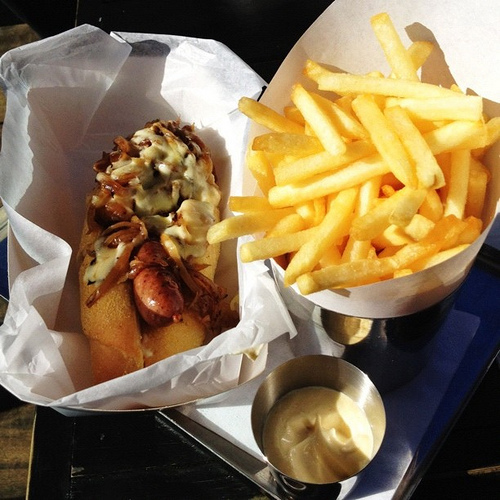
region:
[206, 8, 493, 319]
AN ORDER OF FRENCH FRIES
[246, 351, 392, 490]
A CONTAINER OF SAUCE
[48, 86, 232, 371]
A HOT DOG AND BUN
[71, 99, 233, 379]
A HOT DOG WITH CHEESE AND GRILLED ONIONS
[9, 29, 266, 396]
A HOT DOG ON SOME WAX PAPER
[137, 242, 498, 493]
A METAL SERVING TRAY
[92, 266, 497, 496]
A TRAY ON A TABLE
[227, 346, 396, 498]
A METAL CONTAINER OF SAUCE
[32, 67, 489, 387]
A HOT DOG AND FRIES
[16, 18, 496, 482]
A HOT DOG AND FRIES ON A TRAY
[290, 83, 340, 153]
one French fried potato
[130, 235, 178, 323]
a wiener on a bun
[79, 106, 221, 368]
a loaded hot dog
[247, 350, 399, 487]
dipping sauce for the fries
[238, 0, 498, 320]
a cardboard container of fries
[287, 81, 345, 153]
a single fried potato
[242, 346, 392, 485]
a round metal container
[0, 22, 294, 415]
paper lining for a hot dog container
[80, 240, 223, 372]
a bun of white bread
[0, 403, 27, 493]
the table below the food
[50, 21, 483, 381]
a meal of a hot dog and french fries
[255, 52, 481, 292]
french fries in a paper wrapper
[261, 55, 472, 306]
sticks of fried potatoes laying across each other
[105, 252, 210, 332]
end of a cooked frankfurter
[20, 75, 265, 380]
hot dog with gooey toppings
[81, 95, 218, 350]
fried brown onions added to a hot dog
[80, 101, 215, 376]
cheese melting on top of a hot dog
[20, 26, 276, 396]
hot dog in an open paper wrapper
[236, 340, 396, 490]
small metal container with dipping sauce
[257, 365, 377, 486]
a peak on a creamy condiment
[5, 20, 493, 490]
A tray of food.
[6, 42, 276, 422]
A hot dog in a small paper container.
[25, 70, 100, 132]
Paper.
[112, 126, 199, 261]
Melted cheese is on the hot dog.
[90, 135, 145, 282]
Caramelized onions.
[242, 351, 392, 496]
A small metal bowl that has a dipping sauce in it.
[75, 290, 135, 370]
The bun is golden brown.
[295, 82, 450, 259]
Golden french fries.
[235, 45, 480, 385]
The french fries are in a metal container.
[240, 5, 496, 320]
The french fries are surrounded by paper.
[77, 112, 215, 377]
a hot dog is on a bun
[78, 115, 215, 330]
the hot dog is smothered with cheese and onions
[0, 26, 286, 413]
the hot dog is sitting on a wrapper in a paper plate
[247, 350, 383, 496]
a side order of mayonnaise is on the side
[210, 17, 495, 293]
next to the hot dog is an order of french fries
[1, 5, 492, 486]
the food order is sitting on metal tray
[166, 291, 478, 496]
a napkin is on the tray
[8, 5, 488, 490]
The tray of food is on table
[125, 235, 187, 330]
the hot dog is sticking out from under its dressing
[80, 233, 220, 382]
a hot dog is sitting in the slit of hot dog bread